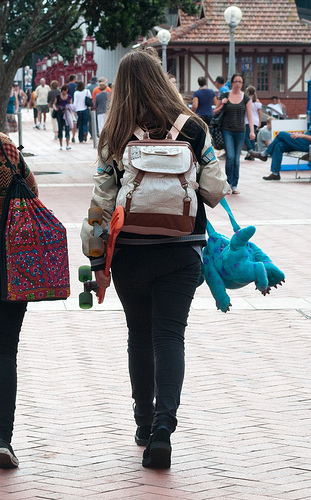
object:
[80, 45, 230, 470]
girl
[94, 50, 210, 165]
hair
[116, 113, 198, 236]
backpack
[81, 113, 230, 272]
jacket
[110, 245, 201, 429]
pants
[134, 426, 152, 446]
shoes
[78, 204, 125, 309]
skateboard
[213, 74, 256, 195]
woman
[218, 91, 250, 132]
tanktop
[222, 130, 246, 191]
bluejeans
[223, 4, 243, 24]
light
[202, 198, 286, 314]
bag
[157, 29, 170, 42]
sphere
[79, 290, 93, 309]
wheel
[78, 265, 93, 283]
wheels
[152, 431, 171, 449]
back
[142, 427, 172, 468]
shoe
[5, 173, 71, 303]
bag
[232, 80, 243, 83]
eyeglasses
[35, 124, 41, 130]
shoe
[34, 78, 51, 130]
man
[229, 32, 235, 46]
part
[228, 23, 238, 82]
pole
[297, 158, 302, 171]
part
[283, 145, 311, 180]
bench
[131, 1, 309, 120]
building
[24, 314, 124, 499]
walkway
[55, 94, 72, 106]
shirt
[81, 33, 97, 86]
posts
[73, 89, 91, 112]
shirt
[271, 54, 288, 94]
windows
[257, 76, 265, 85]
panes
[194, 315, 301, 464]
bricks